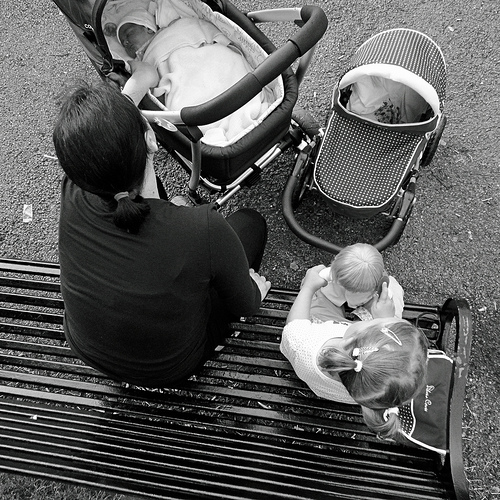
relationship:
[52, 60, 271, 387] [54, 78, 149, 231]
girl has hair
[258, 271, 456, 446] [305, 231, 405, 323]
girl holding doll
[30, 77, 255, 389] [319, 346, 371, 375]
girl has ponytail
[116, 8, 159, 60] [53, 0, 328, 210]
baby in baby carriage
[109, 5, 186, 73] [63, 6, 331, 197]
baby in baby carriage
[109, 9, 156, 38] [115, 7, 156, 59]
white hat on baby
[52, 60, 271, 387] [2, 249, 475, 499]
girl on bench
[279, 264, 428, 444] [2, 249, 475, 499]
girl on bench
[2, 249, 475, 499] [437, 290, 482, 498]
bench on armrest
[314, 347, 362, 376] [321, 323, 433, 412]
pigtail on hair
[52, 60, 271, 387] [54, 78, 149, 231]
girl with hair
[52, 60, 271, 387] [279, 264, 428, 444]
girl with girl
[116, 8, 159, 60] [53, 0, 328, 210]
baby asleep in a baby carriage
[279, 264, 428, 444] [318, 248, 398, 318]
girl playing with doll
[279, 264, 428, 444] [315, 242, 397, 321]
girl holding doll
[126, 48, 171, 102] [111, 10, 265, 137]
hand next to baby